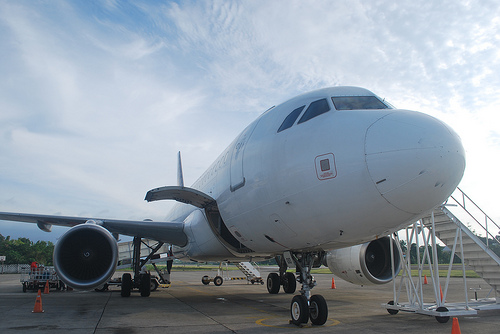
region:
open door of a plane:
[138, 178, 214, 214]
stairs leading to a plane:
[420, 189, 499, 288]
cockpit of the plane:
[273, 91, 389, 128]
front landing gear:
[281, 289, 335, 329]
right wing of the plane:
[3, 205, 191, 255]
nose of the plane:
[363, 105, 475, 221]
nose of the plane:
[293, 62, 475, 253]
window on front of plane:
[281, 80, 403, 137]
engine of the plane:
[23, 197, 136, 309]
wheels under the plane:
[260, 268, 345, 333]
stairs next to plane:
[418, 185, 496, 290]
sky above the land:
[63, 46, 210, 135]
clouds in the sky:
[34, 36, 201, 138]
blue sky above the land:
[95, 23, 242, 79]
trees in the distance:
[0, 226, 66, 263]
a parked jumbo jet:
[15, 70, 498, 322]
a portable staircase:
[345, 176, 487, 319]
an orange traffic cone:
[17, 279, 51, 324]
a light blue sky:
[8, 7, 498, 247]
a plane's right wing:
[0, 179, 232, 304]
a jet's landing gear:
[112, 248, 332, 333]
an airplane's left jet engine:
[314, 226, 426, 292]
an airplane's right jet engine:
[39, 200, 132, 296]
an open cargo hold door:
[137, 150, 219, 225]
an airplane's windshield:
[274, 65, 412, 134]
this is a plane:
[12, 36, 497, 332]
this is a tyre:
[282, 291, 313, 325]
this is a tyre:
[308, 291, 332, 327]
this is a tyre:
[265, 271, 286, 297]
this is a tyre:
[276, 269, 301, 291]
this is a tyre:
[133, 270, 160, 300]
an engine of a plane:
[30, 204, 126, 299]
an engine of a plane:
[324, 229, 422, 296]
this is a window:
[328, 89, 399, 114]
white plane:
[79, 89, 471, 328]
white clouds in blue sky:
[27, 11, 58, 34]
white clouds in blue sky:
[9, 99, 51, 144]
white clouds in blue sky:
[82, 102, 142, 133]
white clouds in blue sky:
[153, 10, 213, 67]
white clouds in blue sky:
[426, 27, 456, 64]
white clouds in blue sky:
[132, 7, 187, 58]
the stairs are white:
[402, 216, 494, 306]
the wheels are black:
[383, 297, 465, 320]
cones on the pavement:
[27, 278, 62, 318]